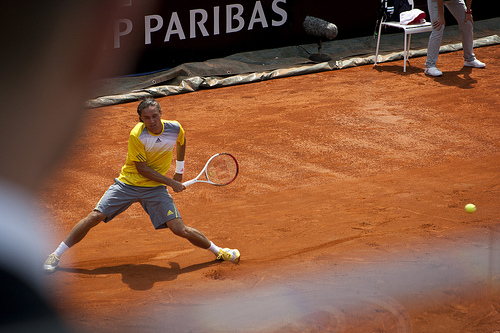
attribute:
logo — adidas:
[166, 209, 172, 217]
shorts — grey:
[93, 175, 179, 231]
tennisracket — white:
[171, 152, 241, 189]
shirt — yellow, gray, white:
[102, 120, 208, 192]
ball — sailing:
[458, 199, 483, 219]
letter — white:
[136, 10, 163, 52]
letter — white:
[163, 5, 187, 46]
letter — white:
[185, 3, 210, 43]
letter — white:
[209, 1, 226, 41]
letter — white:
[223, 1, 247, 34]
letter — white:
[214, 6, 220, 35]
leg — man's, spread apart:
[145, 200, 247, 272]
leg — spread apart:
[37, 187, 125, 273]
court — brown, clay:
[87, 70, 498, 321]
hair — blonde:
[136, 97, 161, 116]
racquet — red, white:
[176, 148, 246, 203]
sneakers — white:
[41, 250, 65, 273]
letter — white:
[243, 1, 272, 32]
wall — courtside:
[0, 1, 497, 93]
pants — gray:
[425, 0, 482, 79]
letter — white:
[194, 0, 220, 38]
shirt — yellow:
[115, 118, 189, 190]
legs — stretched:
[40, 190, 240, 271]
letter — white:
[161, 6, 193, 44]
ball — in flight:
[465, 202, 477, 212]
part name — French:
[139, 0, 290, 54]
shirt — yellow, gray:
[114, 120, 186, 185]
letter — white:
[269, 0, 289, 27]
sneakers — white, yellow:
[18, 203, 288, 290]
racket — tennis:
[177, 150, 240, 192]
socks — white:
[47, 230, 233, 270]